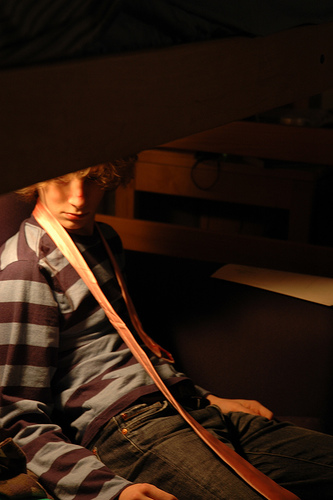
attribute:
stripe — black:
[26, 214, 44, 229]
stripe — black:
[17, 220, 37, 262]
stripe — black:
[0, 260, 46, 281]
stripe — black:
[0, 301, 58, 326]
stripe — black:
[49, 262, 81, 293]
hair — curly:
[91, 160, 136, 196]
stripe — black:
[46, 248, 84, 307]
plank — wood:
[0, 31, 332, 194]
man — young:
[1, 152, 332, 498]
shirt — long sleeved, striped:
[2, 217, 208, 499]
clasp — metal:
[117, 425, 129, 437]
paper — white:
[210, 259, 331, 311]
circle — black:
[186, 153, 231, 192]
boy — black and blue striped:
[2, 154, 331, 497]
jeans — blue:
[91, 395, 331, 498]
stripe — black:
[38, 445, 92, 490]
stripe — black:
[0, 280, 61, 335]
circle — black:
[179, 151, 251, 209]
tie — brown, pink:
[29, 197, 294, 498]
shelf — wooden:
[90, 142, 330, 276]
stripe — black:
[2, 341, 55, 368]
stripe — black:
[16, 431, 74, 463]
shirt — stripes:
[1, 215, 186, 496]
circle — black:
[189, 159, 223, 191]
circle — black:
[194, 156, 220, 194]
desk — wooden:
[124, 119, 328, 270]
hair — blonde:
[5, 161, 113, 203]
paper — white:
[209, 254, 328, 333]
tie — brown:
[20, 189, 305, 493]